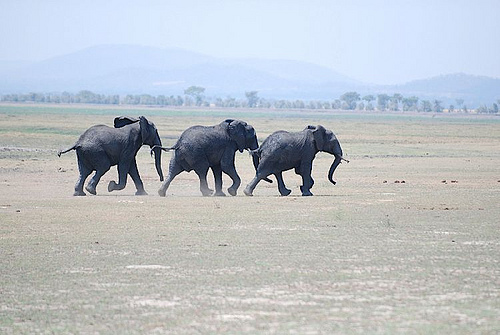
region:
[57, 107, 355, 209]
the elephants are running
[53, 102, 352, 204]
three elephants together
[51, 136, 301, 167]
the elephants have tails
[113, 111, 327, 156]
the elephants have ears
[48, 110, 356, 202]
the elephants are dark grey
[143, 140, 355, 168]
the elephants have trunks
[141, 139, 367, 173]
the elephants have tusks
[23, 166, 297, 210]
the elephants are kicking up dust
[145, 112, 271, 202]
the elephant is in the middle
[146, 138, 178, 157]
this is a tail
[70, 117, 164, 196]
gray elephant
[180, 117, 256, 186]
gray elephant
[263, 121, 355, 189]
gray elephant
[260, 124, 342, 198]
gray elephant running on plain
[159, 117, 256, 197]
gray elephant running on plain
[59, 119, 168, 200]
gray elephant running on plain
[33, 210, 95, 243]
short brown and yellow grass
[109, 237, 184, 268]
short brown and yellow grass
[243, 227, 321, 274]
short brown and yellow grass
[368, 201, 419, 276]
short brown and yellow grass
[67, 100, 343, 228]
three elephants on grass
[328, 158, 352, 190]
trunk of grey elephant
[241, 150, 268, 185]
trunk of grey elephant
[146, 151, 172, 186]
trunk of grey elephant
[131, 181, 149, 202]
foot of grey elephant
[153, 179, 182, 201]
foot of grey elephant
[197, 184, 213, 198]
foot of grey elephant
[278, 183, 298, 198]
foot of grey elephant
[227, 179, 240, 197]
foot of grey elephant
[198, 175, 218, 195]
foot of grey elephant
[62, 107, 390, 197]
three elehants on the move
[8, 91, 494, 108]
trees on th edge of derest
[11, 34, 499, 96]
mountains off in the distance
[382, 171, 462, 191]
roack on the derest floor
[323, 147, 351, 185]
trunk on a elephant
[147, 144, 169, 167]
tail of a elephant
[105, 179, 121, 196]
foot on a elephant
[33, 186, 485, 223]
dusty trail on road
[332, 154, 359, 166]
tusk on a elephant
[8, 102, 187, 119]
greeb grass in the behind elephant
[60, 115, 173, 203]
gray elephant running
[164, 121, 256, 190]
gray elephant running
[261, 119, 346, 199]
gray elephant running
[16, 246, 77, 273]
short green and yellow grass on plain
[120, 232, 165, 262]
short green and yellow grass on plain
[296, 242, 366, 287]
short green and yellow grass on plain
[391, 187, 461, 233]
short green and yellow grass on plain